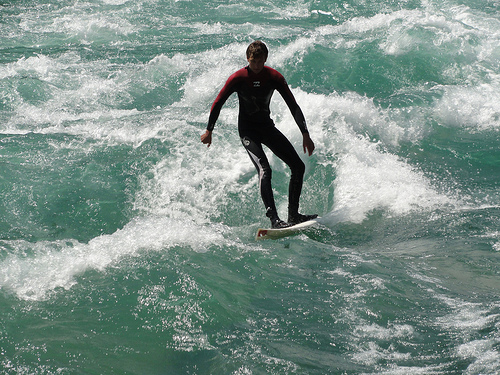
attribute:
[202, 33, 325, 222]
man — surfing, standing, surfer, white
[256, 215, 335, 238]
surfboard — white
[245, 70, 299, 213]
wetsuit — red, black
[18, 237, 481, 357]
ocean — rough, green, choppy, blue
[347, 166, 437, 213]
wave cap — white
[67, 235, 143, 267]
sea foam — white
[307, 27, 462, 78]
wave — white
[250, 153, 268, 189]
stripe — white